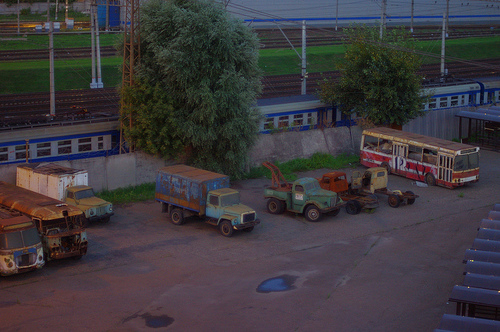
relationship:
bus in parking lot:
[359, 125, 481, 189] [3, 150, 497, 330]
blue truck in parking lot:
[154, 165, 261, 239] [3, 150, 497, 330]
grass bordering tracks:
[5, 33, 495, 88] [0, 24, 497, 59]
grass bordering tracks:
[5, 33, 495, 88] [10, 57, 490, 132]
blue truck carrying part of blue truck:
[154, 163, 261, 236] [154, 163, 261, 236]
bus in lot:
[0, 181, 89, 262] [122, 228, 272, 314]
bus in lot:
[0, 181, 89, 262] [134, 202, 329, 315]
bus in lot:
[359, 127, 481, 189] [2, 140, 498, 330]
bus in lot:
[359, 127, 481, 189] [312, 151, 440, 298]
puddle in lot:
[255, 274, 297, 293] [2, 140, 498, 330]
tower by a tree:
[116, 1, 147, 156] [123, 1, 265, 181]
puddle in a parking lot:
[254, 272, 297, 293] [3, 150, 497, 330]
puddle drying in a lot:
[129, 301, 174, 328] [176, 203, 327, 304]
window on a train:
[276, 107, 287, 126] [2, 73, 492, 185]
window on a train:
[73, 135, 93, 153] [2, 73, 492, 185]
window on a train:
[54, 137, 79, 158] [2, 73, 492, 185]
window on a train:
[14, 146, 36, 164] [2, 73, 492, 185]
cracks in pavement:
[338, 233, 390, 283] [318, 234, 383, 279]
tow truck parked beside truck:
[262, 160, 344, 222] [309, 169, 377, 218]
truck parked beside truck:
[309, 169, 377, 218] [343, 166, 419, 210]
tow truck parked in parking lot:
[262, 160, 344, 222] [3, 150, 497, 330]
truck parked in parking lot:
[309, 169, 377, 218] [3, 150, 497, 330]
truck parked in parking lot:
[343, 166, 419, 210] [3, 150, 497, 330]